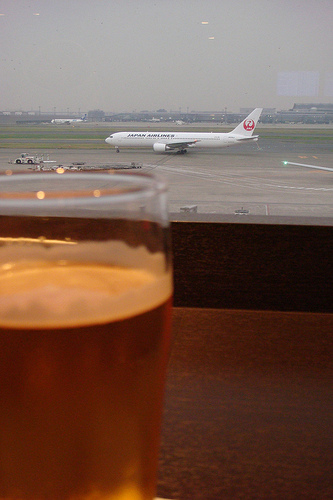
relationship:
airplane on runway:
[104, 107, 264, 155] [2, 142, 330, 161]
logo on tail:
[243, 118, 255, 131] [233, 105, 271, 138]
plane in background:
[34, 100, 81, 136] [10, 14, 329, 153]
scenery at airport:
[1, 103, 332, 131] [1, 101, 332, 224]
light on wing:
[282, 156, 293, 171] [280, 159, 330, 182]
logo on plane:
[239, 106, 263, 144] [122, 125, 262, 146]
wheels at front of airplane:
[115, 148, 120, 152] [104, 107, 264, 155]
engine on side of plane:
[158, 139, 173, 158] [95, 102, 273, 166]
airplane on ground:
[100, 103, 273, 155] [163, 157, 238, 181]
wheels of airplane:
[116, 148, 119, 153] [100, 103, 273, 155]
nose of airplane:
[104, 137, 109, 145] [100, 103, 273, 155]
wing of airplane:
[231, 109, 261, 132] [100, 103, 273, 155]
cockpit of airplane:
[106, 133, 113, 139] [93, 118, 272, 168]